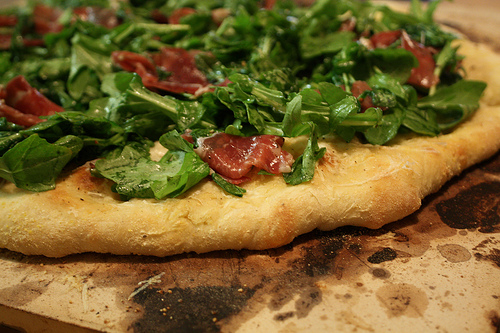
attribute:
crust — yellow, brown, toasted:
[1, 41, 497, 258]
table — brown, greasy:
[0, 155, 498, 331]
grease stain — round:
[375, 281, 429, 321]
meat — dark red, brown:
[189, 131, 295, 185]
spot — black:
[128, 281, 262, 332]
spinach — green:
[0, 134, 69, 192]